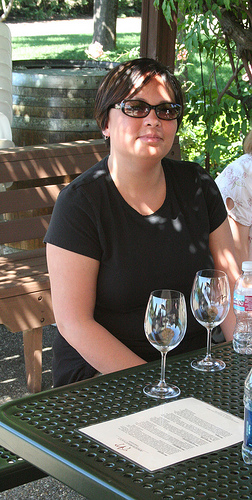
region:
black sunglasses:
[109, 94, 186, 122]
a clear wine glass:
[145, 283, 185, 397]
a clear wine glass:
[191, 266, 228, 369]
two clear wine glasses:
[143, 260, 228, 397]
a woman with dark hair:
[82, 59, 183, 164]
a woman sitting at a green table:
[55, 59, 238, 424]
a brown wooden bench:
[0, 149, 57, 380]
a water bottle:
[241, 365, 250, 462]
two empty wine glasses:
[147, 267, 230, 396]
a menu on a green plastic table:
[80, 386, 237, 463]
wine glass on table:
[136, 279, 202, 400]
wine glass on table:
[189, 259, 233, 382]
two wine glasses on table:
[142, 256, 240, 402]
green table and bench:
[0, 366, 250, 498]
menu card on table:
[74, 383, 249, 489]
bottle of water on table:
[232, 253, 251, 365]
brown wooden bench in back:
[0, 131, 129, 400]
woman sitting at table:
[22, 40, 249, 470]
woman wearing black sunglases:
[114, 89, 186, 129]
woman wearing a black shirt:
[48, 132, 233, 376]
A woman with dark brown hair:
[92, 57, 188, 167]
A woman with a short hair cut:
[93, 55, 184, 167]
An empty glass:
[142, 287, 189, 400]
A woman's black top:
[41, 157, 229, 357]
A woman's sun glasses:
[108, 97, 185, 121]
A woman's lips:
[135, 131, 164, 144]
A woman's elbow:
[48, 288, 108, 344]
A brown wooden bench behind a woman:
[2, 139, 102, 393]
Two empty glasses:
[143, 266, 233, 399]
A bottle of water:
[232, 259, 251, 357]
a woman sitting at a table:
[37, 53, 250, 364]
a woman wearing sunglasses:
[115, 96, 186, 125]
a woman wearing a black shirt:
[50, 158, 224, 347]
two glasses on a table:
[145, 269, 228, 397]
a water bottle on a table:
[234, 258, 251, 357]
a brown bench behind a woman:
[0, 138, 124, 384]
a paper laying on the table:
[71, 389, 251, 481]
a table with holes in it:
[8, 334, 247, 498]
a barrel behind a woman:
[11, 43, 137, 142]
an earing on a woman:
[103, 131, 109, 141]